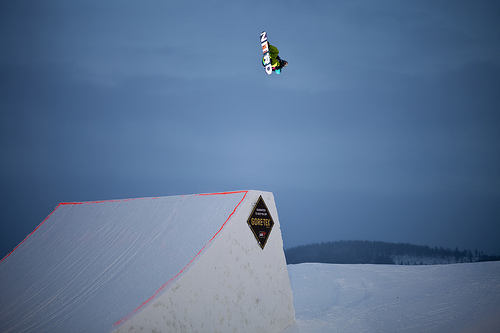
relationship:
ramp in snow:
[2, 188, 295, 330] [286, 262, 497, 331]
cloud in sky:
[0, 0, 500, 258] [1, 2, 498, 254]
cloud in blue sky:
[0, 0, 500, 258] [8, 12, 479, 230]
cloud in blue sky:
[0, 0, 500, 258] [0, 0, 500, 258]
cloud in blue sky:
[0, 0, 500, 258] [342, 53, 444, 181]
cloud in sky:
[0, 0, 500, 258] [22, 9, 492, 189]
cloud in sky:
[0, 0, 500, 258] [9, 19, 498, 204]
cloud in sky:
[0, 0, 500, 258] [14, 46, 498, 186]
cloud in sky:
[0, 0, 500, 258] [398, 169, 477, 236]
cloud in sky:
[26, 125, 479, 198] [1, 2, 498, 254]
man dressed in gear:
[262, 45, 289, 75] [260, 43, 286, 80]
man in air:
[262, 45, 289, 75] [167, 45, 177, 58]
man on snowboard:
[244, 22, 303, 83] [255, 22, 273, 72]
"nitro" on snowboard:
[259, 31, 271, 75] [258, 29, 273, 76]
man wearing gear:
[262, 45, 289, 75] [267, 45, 287, 69]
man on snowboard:
[262, 45, 289, 75] [259, 32, 271, 75]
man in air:
[262, 45, 289, 75] [318, 100, 434, 163]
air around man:
[318, 100, 434, 163] [262, 45, 289, 75]